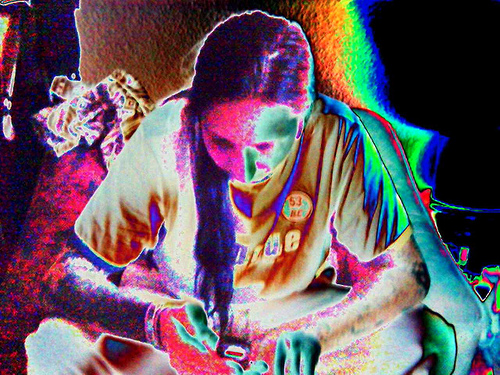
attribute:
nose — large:
[226, 147, 257, 181]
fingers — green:
[271, 329, 319, 371]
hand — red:
[155, 305, 235, 373]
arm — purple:
[53, 260, 182, 341]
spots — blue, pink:
[57, 258, 149, 321]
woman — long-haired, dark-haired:
[162, 13, 437, 351]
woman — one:
[100, 20, 426, 347]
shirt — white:
[138, 124, 402, 307]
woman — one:
[67, 26, 429, 365]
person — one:
[84, 26, 451, 364]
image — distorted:
[28, 30, 473, 372]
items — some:
[31, 79, 142, 160]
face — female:
[195, 78, 301, 198]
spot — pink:
[209, 100, 257, 158]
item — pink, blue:
[21, 160, 83, 310]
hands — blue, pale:
[163, 300, 337, 373]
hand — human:
[149, 289, 230, 359]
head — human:
[189, 13, 314, 190]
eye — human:
[203, 128, 236, 151]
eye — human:
[253, 132, 287, 159]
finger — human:
[288, 332, 309, 372]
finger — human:
[264, 340, 283, 372]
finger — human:
[283, 334, 304, 373]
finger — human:
[168, 310, 228, 351]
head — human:
[182, 16, 326, 197]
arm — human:
[46, 139, 203, 349]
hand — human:
[133, 302, 233, 363]